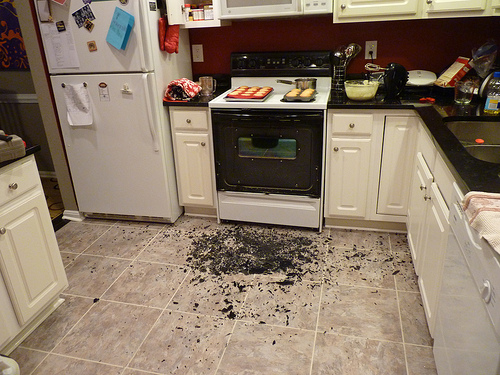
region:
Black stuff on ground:
[171, 213, 337, 318]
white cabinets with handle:
[3, 156, 71, 318]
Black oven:
[223, 111, 328, 196]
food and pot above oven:
[228, 65, 335, 107]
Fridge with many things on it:
[51, 5, 152, 170]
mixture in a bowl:
[335, 59, 415, 107]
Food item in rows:
[223, 73, 277, 105]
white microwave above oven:
[211, 3, 338, 28]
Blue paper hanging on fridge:
[93, 9, 146, 64]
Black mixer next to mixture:
[368, 56, 418, 96]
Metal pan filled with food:
[280, 82, 328, 109]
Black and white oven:
[190, 41, 352, 247]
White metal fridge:
[17, 0, 219, 225]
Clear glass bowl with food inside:
[339, 68, 386, 106]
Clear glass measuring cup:
[450, 73, 482, 112]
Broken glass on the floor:
[136, 211, 366, 333]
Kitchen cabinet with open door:
[150, 0, 237, 33]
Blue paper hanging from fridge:
[99, 0, 143, 61]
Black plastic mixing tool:
[358, 52, 416, 117]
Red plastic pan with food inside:
[218, 73, 278, 113]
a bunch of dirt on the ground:
[171, 227, 348, 327]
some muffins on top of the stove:
[222, 83, 317, 104]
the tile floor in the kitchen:
[58, 220, 423, 372]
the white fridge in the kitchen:
[31, 6, 173, 229]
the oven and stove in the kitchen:
[208, 51, 319, 225]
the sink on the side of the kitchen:
[443, 116, 499, 180]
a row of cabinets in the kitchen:
[341, 117, 449, 334]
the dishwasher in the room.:
[409, 188, 499, 373]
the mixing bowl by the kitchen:
[346, 61, 403, 104]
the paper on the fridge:
[54, 80, 101, 138]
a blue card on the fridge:
[105, 3, 137, 59]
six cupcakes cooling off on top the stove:
[280, 82, 317, 104]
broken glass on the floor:
[174, 229, 360, 309]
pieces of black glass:
[176, 232, 330, 334]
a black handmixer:
[365, 58, 412, 105]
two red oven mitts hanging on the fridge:
[156, 11, 188, 58]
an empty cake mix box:
[432, 47, 474, 92]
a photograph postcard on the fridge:
[70, 4, 102, 30]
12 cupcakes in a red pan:
[228, 80, 274, 105]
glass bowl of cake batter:
[342, 76, 381, 104]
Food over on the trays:
[227, 75, 318, 102]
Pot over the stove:
[274, 72, 324, 92]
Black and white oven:
[211, 45, 335, 235]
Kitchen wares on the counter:
[333, 38, 363, 101]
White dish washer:
[426, 193, 499, 373]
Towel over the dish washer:
[459, 183, 496, 257]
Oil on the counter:
[478, 64, 499, 121]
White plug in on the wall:
[363, 35, 381, 65]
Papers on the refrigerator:
[35, 0, 142, 131]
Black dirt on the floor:
[72, 210, 417, 374]